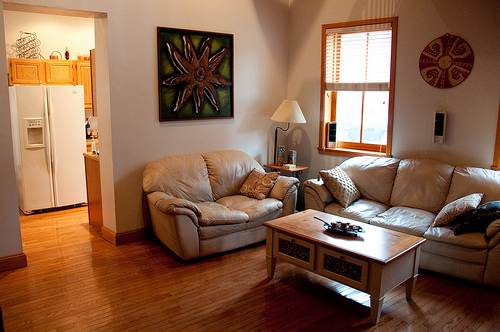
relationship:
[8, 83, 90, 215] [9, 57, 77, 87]
fridge has storage space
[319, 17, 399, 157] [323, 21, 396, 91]
window has mini blinds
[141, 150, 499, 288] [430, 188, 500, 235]
couch has two pillows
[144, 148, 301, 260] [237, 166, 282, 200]
love seat has one pillow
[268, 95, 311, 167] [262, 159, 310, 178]
lamp on end table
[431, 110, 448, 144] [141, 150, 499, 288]
speaker above couch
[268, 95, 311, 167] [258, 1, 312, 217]
lamp in corner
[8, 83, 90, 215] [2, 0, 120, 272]
refrigerator in background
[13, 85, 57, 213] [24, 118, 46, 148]
door has a water dispenser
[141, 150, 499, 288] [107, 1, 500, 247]
couch by a wall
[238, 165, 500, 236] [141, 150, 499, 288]
pillows are on some couches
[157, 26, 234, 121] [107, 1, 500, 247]
picture on a wall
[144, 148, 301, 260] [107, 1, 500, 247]
loveseat against a wall